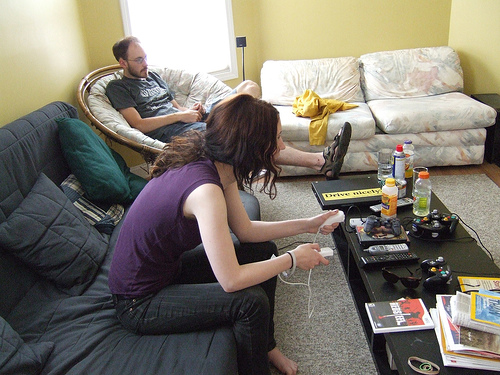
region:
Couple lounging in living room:
[92, 32, 284, 335]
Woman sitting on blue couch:
[105, 91, 294, 338]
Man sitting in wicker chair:
[104, 33, 181, 143]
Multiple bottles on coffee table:
[380, 138, 435, 220]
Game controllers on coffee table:
[365, 208, 461, 290]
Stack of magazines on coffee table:
[430, 294, 497, 369]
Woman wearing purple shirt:
[122, 94, 282, 289]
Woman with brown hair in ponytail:
[152, 91, 284, 193]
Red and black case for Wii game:
[363, 296, 428, 334]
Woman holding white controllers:
[204, 93, 350, 271]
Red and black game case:
[365, 298, 429, 334]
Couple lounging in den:
[102, 35, 298, 327]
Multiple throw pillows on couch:
[29, 142, 121, 277]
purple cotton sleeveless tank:
[109, 158, 226, 296]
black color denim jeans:
[118, 237, 278, 360]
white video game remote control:
[321, 209, 345, 229]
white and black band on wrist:
[286, 250, 298, 275]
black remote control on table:
[360, 250, 418, 267]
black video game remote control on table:
[424, 255, 452, 289]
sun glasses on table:
[381, 266, 423, 291]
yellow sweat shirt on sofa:
[293, 91, 358, 143]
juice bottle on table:
[381, 177, 399, 219]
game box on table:
[361, 297, 436, 332]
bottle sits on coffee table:
[410, 167, 432, 214]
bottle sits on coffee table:
[379, 177, 400, 218]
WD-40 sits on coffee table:
[392, 143, 405, 180]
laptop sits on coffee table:
[310, 175, 382, 210]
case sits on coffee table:
[360, 295, 431, 335]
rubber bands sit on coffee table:
[406, 355, 442, 374]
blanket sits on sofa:
[287, 87, 359, 145]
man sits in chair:
[107, 34, 350, 181]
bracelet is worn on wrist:
[285, 247, 295, 276]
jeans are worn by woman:
[110, 238, 279, 374]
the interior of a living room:
[0, 0, 499, 374]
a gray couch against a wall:
[0, 100, 278, 373]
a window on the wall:
[119, 0, 238, 82]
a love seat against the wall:
[260, 45, 497, 176]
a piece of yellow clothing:
[290, 88, 358, 145]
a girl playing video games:
[107, 93, 339, 373]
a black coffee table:
[329, 176, 499, 373]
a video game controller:
[418, 255, 452, 289]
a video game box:
[364, 297, 434, 332]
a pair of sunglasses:
[380, 265, 423, 289]